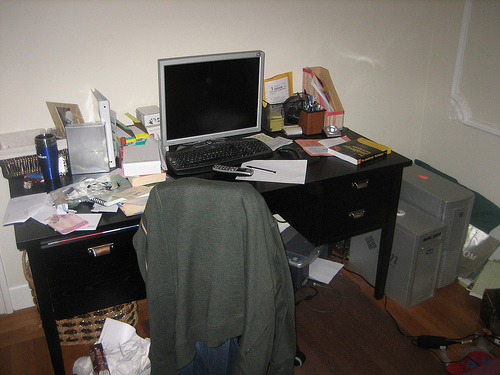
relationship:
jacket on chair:
[195, 197, 244, 262] [280, 218, 385, 367]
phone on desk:
[49, 162, 133, 230] [12, 109, 383, 280]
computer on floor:
[400, 180, 466, 283] [367, 274, 464, 307]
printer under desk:
[279, 236, 390, 302] [12, 109, 383, 280]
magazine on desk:
[288, 62, 368, 146] [12, 109, 383, 280]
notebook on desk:
[71, 110, 138, 170] [12, 109, 383, 280]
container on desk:
[33, 128, 68, 169] [12, 109, 383, 280]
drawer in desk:
[328, 141, 407, 249] [12, 109, 383, 280]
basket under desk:
[37, 302, 125, 343] [12, 109, 383, 280]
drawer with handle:
[328, 141, 407, 249] [348, 177, 374, 192]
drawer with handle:
[328, 141, 407, 249] [348, 206, 365, 221]